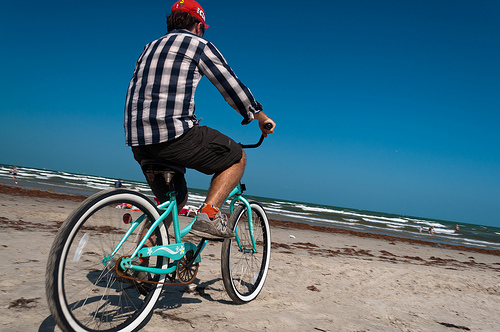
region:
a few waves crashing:
[293, 197, 453, 237]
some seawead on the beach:
[293, 243, 490, 276]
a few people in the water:
[413, 218, 468, 240]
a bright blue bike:
[36, 155, 284, 326]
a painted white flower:
[142, 244, 157, 259]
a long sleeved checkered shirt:
[120, 29, 264, 145]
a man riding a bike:
[44, 0, 275, 322]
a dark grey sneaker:
[191, 210, 240, 240]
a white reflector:
[71, 231, 96, 263]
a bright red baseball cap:
[168, 0, 213, 31]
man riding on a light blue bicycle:
[44, 0, 274, 330]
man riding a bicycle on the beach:
[44, 0, 272, 330]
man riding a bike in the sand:
[44, 0, 272, 329]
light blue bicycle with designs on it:
[43, 120, 272, 329]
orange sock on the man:
[196, 204, 221, 223]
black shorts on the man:
[131, 126, 242, 204]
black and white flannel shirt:
[123, 34, 260, 148]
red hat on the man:
[168, 0, 210, 29]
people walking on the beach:
[1, 163, 133, 194]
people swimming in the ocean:
[413, 220, 499, 250]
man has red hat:
[150, 2, 234, 27]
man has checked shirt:
[111, 19, 211, 160]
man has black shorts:
[126, 123, 243, 196]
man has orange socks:
[194, 193, 232, 219]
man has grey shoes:
[192, 209, 249, 253]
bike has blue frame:
[130, 164, 285, 294]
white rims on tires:
[67, 176, 193, 330]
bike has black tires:
[57, 166, 164, 326]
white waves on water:
[242, 166, 445, 231]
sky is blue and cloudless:
[230, 1, 482, 169]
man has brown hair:
[143, 7, 215, 29]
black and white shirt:
[137, 21, 259, 135]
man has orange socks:
[177, 205, 232, 240]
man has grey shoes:
[195, 209, 234, 239]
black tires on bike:
[224, 201, 279, 317]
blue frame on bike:
[107, 180, 292, 309]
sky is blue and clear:
[318, 6, 443, 169]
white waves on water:
[287, 211, 449, 236]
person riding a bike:
[19, 3, 287, 329]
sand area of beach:
[305, 267, 471, 314]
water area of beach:
[298, 202, 495, 239]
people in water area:
[417, 219, 439, 236]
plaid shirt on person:
[122, 34, 256, 134]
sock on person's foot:
[201, 202, 220, 220]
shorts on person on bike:
[108, 123, 242, 173]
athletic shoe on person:
[191, 215, 234, 238]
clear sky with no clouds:
[293, 19, 480, 178]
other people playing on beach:
[6, 163, 28, 185]